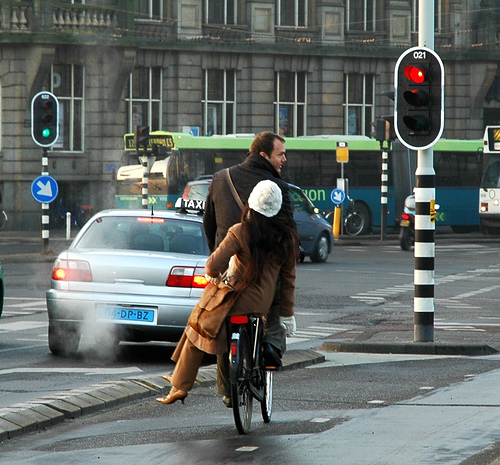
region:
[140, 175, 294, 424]
female riding passenger on the back of a bicycle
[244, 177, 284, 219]
female bike riders hat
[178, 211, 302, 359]
female bike riders coat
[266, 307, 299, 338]
female bike riders glove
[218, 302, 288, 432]
bicycle carrying two people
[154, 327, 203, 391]
female bike riders pants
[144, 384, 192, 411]
female bike rides shoes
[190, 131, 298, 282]
male bike rider in the front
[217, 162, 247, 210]
satchel strap on the man riding bike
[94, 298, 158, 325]
license plate on back of grey car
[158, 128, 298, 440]
Man and a woman on a bicycle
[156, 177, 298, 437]
Women sitting sideways on the back of a bicycle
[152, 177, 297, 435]
Woman wearing high heels on a bicycle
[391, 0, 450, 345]
Black striped traffic light pole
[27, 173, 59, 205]
Circular blue sign with a white arrow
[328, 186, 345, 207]
Blue and white directional traffic sign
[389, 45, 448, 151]
Red traffic light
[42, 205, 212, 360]
Silver car stopped at an intersection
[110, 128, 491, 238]
Very large blue bus with a green roof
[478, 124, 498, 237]
Front of a white bus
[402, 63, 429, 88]
A red lit traffic light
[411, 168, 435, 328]
A black and white striped traffic light pole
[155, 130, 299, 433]
A man and woman riding a bicycle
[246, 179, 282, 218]
A white plush cap on a woman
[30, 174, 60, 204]
A blue and whiet arrow sign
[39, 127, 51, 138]
A green lit traffic light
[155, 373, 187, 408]
Light brown colored high heels on a woman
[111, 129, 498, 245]
A green and black public bus on the road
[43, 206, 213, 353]
A small grey car stopped at a red light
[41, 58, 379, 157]
A row of windows on a building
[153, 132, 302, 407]
Couple riding on a bicycle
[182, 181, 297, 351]
Woman wearing brown coat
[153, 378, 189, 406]
Woman wearing brown heels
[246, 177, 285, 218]
Woman wearing white hat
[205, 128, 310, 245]
Man wearing black coat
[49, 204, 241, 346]
Silver car on street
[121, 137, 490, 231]
Blue and green bus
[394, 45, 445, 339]
Traffic lights on pole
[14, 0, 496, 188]
Building on the street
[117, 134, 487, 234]
Bus infront of building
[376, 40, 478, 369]
traffic stop light indicator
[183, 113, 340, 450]
couple riding a bike in the bike lane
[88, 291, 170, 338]
license plate for identification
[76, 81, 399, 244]
commuter bus in background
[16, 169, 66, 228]
arrow indicator where vehicle is to stop at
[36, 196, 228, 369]
silver taxi cab for transportation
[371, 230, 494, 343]
pedestrian walkways for safety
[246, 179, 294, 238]
wool cap for warmth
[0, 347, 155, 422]
right turn directional arrow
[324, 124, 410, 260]
multiple traffic indication signs